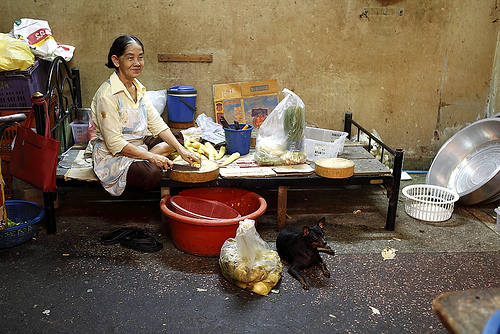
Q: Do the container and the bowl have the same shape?
A: Yes, both the container and the bowl are round.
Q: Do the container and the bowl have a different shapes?
A: No, both the container and the bowl are round.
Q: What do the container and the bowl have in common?
A: The shape, both the container and the bowl are round.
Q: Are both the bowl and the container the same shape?
A: Yes, both the bowl and the container are round.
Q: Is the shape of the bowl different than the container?
A: No, both the bowl and the container are round.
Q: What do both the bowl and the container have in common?
A: The shape, both the bowl and the container are round.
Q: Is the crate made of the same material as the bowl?
A: No, the crate is made of plastic and the bowl is made of metal.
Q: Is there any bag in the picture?
A: Yes, there is a bag.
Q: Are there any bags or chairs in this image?
A: Yes, there is a bag.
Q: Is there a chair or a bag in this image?
A: Yes, there is a bag.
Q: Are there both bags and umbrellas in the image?
A: No, there is a bag but no umbrellas.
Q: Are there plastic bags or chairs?
A: Yes, there is a plastic bag.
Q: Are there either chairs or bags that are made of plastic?
A: Yes, the bag is made of plastic.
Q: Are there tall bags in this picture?
A: Yes, there is a tall bag.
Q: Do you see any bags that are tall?
A: Yes, there is a bag that is tall.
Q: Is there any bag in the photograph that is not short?
A: Yes, there is a tall bag.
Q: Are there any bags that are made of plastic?
A: Yes, there is a bag that is made of plastic.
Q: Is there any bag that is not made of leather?
A: Yes, there is a bag that is made of plastic.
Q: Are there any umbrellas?
A: No, there are no umbrellas.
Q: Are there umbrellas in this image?
A: No, there are no umbrellas.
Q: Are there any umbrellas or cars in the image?
A: No, there are no umbrellas or cars.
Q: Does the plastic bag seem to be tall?
A: Yes, the bag is tall.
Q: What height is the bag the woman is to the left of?
A: The bag is tall.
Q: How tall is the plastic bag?
A: The bag is tall.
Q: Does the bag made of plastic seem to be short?
A: No, the bag is tall.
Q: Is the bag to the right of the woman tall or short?
A: The bag is tall.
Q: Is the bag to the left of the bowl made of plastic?
A: Yes, the bag is made of plastic.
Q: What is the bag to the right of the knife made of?
A: The bag is made of plastic.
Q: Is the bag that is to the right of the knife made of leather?
A: No, the bag is made of plastic.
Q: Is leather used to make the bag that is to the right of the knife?
A: No, the bag is made of plastic.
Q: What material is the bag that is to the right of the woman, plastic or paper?
A: The bag is made of plastic.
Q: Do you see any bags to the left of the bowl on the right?
A: Yes, there is a bag to the left of the bowl.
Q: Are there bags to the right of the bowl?
A: No, the bag is to the left of the bowl.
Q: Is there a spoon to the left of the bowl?
A: No, there is a bag to the left of the bowl.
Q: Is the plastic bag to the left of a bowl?
A: Yes, the bag is to the left of a bowl.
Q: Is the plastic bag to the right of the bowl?
A: No, the bag is to the left of the bowl.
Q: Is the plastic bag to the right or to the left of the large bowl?
A: The bag is to the left of the bowl.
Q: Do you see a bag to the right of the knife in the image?
A: Yes, there is a bag to the right of the knife.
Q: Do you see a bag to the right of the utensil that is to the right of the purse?
A: Yes, there is a bag to the right of the knife.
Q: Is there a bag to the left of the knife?
A: No, the bag is to the right of the knife.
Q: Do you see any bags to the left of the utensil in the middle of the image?
A: No, the bag is to the right of the knife.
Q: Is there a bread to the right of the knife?
A: No, there is a bag to the right of the knife.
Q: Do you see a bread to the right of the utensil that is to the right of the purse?
A: No, there is a bag to the right of the knife.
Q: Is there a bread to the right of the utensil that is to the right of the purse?
A: No, there is a bag to the right of the knife.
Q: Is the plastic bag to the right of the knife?
A: Yes, the bag is to the right of the knife.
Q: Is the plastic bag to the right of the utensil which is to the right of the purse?
A: Yes, the bag is to the right of the knife.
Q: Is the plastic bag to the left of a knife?
A: No, the bag is to the right of a knife.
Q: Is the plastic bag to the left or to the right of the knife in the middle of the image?
A: The bag is to the right of the knife.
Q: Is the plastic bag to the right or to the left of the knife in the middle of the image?
A: The bag is to the right of the knife.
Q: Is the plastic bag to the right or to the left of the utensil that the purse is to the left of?
A: The bag is to the right of the knife.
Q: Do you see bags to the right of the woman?
A: Yes, there is a bag to the right of the woman.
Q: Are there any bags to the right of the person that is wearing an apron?
A: Yes, there is a bag to the right of the woman.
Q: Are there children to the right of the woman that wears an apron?
A: No, there is a bag to the right of the woman.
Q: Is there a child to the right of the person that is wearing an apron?
A: No, there is a bag to the right of the woman.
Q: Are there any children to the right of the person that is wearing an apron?
A: No, there is a bag to the right of the woman.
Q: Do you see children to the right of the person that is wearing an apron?
A: No, there is a bag to the right of the woman.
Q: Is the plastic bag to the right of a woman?
A: Yes, the bag is to the right of a woman.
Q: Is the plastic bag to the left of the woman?
A: No, the bag is to the right of the woman.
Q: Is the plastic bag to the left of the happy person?
A: No, the bag is to the right of the woman.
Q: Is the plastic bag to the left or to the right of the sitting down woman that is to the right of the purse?
A: The bag is to the right of the woman.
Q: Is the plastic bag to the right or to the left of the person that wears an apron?
A: The bag is to the right of the woman.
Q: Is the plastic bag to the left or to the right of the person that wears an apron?
A: The bag is to the right of the woman.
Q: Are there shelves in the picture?
A: No, there are no shelves.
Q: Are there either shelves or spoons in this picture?
A: No, there are no shelves or spoons.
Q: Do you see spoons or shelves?
A: No, there are no shelves or spoons.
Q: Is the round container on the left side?
A: Yes, the container is on the left of the image.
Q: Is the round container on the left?
A: Yes, the container is on the left of the image.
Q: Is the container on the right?
A: No, the container is on the left of the image.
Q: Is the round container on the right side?
A: No, the container is on the left of the image.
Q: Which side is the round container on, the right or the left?
A: The container is on the left of the image.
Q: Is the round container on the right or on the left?
A: The container is on the left of the image.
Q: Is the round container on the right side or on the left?
A: The container is on the left of the image.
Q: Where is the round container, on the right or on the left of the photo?
A: The container is on the left of the image.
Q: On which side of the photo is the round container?
A: The container is on the left of the image.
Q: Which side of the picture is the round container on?
A: The container is on the left of the image.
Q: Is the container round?
A: Yes, the container is round.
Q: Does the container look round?
A: Yes, the container is round.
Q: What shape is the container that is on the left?
A: The container is round.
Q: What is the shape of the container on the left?
A: The container is round.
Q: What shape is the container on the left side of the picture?
A: The container is round.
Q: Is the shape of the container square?
A: No, the container is round.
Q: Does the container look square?
A: No, the container is round.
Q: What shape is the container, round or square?
A: The container is round.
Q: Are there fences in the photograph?
A: No, there are no fences.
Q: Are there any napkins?
A: No, there are no napkins.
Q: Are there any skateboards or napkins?
A: No, there are no napkins or skateboards.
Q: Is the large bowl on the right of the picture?
A: Yes, the bowl is on the right of the image.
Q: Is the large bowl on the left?
A: No, the bowl is on the right of the image.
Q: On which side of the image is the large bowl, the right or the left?
A: The bowl is on the right of the image.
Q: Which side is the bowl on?
A: The bowl is on the right of the image.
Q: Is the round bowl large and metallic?
A: Yes, the bowl is large and metallic.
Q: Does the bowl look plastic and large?
A: No, the bowl is large but metallic.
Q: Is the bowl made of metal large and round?
A: Yes, the bowl is large and round.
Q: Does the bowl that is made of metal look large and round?
A: Yes, the bowl is large and round.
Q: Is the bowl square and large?
A: No, the bowl is large but round.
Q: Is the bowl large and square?
A: No, the bowl is large but round.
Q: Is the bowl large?
A: Yes, the bowl is large.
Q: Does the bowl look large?
A: Yes, the bowl is large.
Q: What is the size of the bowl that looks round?
A: The bowl is large.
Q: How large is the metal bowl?
A: The bowl is large.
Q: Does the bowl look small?
A: No, the bowl is large.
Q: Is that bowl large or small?
A: The bowl is large.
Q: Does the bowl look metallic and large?
A: Yes, the bowl is metallic and large.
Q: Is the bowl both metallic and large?
A: Yes, the bowl is metallic and large.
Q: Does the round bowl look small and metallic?
A: No, the bowl is metallic but large.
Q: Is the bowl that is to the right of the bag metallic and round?
A: Yes, the bowl is metallic and round.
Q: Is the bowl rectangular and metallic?
A: No, the bowl is metallic but round.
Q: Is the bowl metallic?
A: Yes, the bowl is metallic.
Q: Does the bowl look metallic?
A: Yes, the bowl is metallic.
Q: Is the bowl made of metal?
A: Yes, the bowl is made of metal.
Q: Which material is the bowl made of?
A: The bowl is made of metal.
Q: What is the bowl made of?
A: The bowl is made of metal.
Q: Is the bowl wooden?
A: No, the bowl is metallic.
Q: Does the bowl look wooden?
A: No, the bowl is metallic.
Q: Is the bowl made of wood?
A: No, the bowl is made of metal.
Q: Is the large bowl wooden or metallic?
A: The bowl is metallic.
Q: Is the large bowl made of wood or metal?
A: The bowl is made of metal.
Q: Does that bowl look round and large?
A: Yes, the bowl is round and large.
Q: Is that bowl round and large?
A: Yes, the bowl is round and large.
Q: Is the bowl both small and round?
A: No, the bowl is round but large.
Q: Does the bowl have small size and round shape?
A: No, the bowl is round but large.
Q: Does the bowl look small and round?
A: No, the bowl is round but large.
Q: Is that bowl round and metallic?
A: Yes, the bowl is round and metallic.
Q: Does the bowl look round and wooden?
A: No, the bowl is round but metallic.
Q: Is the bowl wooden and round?
A: No, the bowl is round but metallic.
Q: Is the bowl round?
A: Yes, the bowl is round.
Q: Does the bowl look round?
A: Yes, the bowl is round.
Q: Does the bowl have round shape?
A: Yes, the bowl is round.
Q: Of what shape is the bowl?
A: The bowl is round.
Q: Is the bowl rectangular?
A: No, the bowl is round.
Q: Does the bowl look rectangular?
A: No, the bowl is round.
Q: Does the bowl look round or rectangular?
A: The bowl is round.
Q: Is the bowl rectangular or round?
A: The bowl is round.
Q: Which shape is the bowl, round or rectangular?
A: The bowl is round.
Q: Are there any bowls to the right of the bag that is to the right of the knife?
A: Yes, there is a bowl to the right of the bag.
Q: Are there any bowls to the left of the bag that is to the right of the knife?
A: No, the bowl is to the right of the bag.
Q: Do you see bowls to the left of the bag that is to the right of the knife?
A: No, the bowl is to the right of the bag.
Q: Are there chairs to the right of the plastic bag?
A: No, there is a bowl to the right of the bag.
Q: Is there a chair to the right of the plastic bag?
A: No, there is a bowl to the right of the bag.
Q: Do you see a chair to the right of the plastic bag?
A: No, there is a bowl to the right of the bag.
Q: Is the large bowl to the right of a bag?
A: Yes, the bowl is to the right of a bag.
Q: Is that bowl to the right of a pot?
A: No, the bowl is to the right of a bag.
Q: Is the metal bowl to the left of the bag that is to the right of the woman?
A: No, the bowl is to the right of the bag.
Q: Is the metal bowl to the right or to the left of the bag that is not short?
A: The bowl is to the right of the bag.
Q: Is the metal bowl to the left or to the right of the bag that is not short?
A: The bowl is to the right of the bag.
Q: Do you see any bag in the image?
A: Yes, there is a bag.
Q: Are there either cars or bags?
A: Yes, there is a bag.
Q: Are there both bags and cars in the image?
A: No, there is a bag but no cars.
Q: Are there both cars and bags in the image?
A: No, there is a bag but no cars.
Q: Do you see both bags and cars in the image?
A: No, there is a bag but no cars.